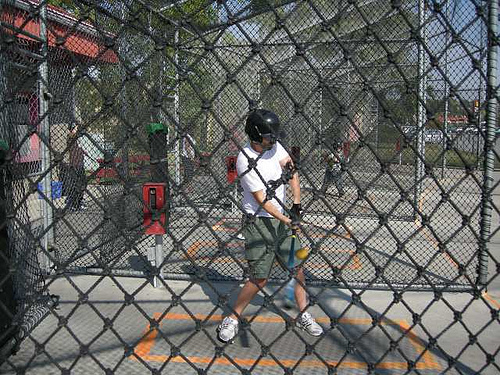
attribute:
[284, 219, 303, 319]
bat — batter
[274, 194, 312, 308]
bat — blue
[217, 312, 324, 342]
shoes — white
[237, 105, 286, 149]
helmet — batting, black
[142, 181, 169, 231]
box — red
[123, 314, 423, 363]
lines — yellow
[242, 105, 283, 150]
helmet — black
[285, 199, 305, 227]
glove — batting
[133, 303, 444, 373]
box — orange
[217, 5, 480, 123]
sky — blue